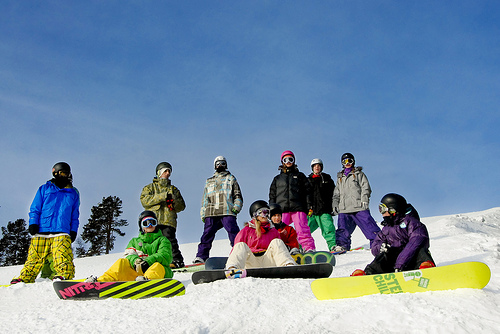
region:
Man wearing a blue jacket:
[7, 158, 85, 287]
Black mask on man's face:
[43, 158, 77, 192]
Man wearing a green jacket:
[135, 156, 192, 267]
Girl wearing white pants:
[224, 199, 297, 276]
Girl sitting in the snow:
[309, 191, 492, 300]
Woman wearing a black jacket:
[262, 146, 317, 252]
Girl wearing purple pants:
[320, 148, 384, 249]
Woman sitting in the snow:
[83, 205, 189, 296]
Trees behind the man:
[0, 196, 127, 266]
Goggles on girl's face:
[129, 215, 161, 230]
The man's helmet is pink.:
[273, 150, 301, 173]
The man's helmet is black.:
[49, 160, 76, 185]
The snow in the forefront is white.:
[213, 303, 295, 330]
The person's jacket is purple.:
[368, 188, 432, 267]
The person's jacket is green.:
[123, 211, 176, 273]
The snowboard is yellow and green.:
[306, 258, 495, 303]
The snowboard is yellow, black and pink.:
[48, 275, 191, 305]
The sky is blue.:
[240, 7, 370, 78]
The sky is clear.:
[246, 6, 379, 75]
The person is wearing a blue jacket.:
[28, 151, 78, 240]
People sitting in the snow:
[45, 190, 491, 305]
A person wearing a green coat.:
[96, 202, 176, 289]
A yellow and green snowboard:
[308, 258, 490, 303]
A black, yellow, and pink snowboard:
[47, 276, 187, 302]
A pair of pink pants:
[282, 212, 314, 253]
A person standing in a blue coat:
[22, 154, 90, 285]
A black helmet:
[380, 191, 412, 213]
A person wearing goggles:
[87, 200, 178, 294]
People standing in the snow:
[15, 138, 388, 288]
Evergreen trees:
[4, 187, 126, 277]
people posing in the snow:
[22, 127, 489, 320]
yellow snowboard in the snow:
[309, 252, 487, 308]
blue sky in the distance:
[243, 38, 475, 143]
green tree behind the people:
[83, 183, 129, 277]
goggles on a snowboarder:
[136, 213, 163, 229]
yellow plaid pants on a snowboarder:
[10, 225, 99, 287]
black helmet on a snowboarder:
[383, 188, 411, 218]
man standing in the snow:
[188, 147, 250, 249]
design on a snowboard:
[60, 276, 173, 300]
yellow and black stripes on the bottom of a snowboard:
[97, 278, 185, 300]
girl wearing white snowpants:
[223, 239, 295, 268]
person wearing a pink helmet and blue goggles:
[277, 149, 296, 168]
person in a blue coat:
[26, 178, 82, 241]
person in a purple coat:
[362, 218, 431, 270]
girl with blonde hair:
[243, 206, 263, 243]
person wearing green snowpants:
[310, 209, 334, 253]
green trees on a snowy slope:
[1, 193, 129, 265]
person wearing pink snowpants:
[276, 207, 318, 259]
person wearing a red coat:
[272, 222, 296, 254]